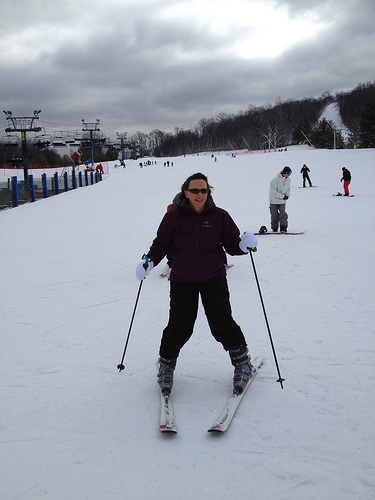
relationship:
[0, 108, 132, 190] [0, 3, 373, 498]
chair lift at ski resort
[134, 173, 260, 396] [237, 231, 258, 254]
skier wearing glove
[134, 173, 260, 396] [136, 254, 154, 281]
skier wearing glove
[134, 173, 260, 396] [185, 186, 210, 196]
skier wearing sunglasses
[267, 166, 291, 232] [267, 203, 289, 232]
skier wearing pants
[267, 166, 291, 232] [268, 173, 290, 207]
skier wearing jacket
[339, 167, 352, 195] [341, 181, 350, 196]
skier wearing pants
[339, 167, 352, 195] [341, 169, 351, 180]
skier wearing jacket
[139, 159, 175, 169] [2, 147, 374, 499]
skiers up on slope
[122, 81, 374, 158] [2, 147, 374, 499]
trees to right of slope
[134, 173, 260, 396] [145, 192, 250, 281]
skier wearing jacket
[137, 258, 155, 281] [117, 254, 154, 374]
hand holding ski pole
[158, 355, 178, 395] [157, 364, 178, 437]
ski boot on top of ski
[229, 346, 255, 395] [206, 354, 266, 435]
ski boot on top of ski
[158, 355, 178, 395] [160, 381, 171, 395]
ski boot placed in binder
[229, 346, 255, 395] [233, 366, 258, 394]
ski boot placed in binder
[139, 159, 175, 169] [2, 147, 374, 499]
skiers located on slope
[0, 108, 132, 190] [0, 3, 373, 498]
chair lift located in ski resort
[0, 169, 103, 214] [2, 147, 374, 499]
fence to left of slope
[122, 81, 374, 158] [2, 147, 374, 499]
trees next to slope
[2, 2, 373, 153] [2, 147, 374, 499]
sky above slope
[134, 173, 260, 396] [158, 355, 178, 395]
skier wearing ski boot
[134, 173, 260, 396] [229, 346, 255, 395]
skier wearing ski boot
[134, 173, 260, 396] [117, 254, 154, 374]
skier holding ski pole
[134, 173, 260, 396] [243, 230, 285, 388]
skier holding ski pole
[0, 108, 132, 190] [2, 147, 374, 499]
chair lift above slope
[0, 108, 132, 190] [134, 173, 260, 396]
chair lift to left of skier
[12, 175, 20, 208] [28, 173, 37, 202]
post next to post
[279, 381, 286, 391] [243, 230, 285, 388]
point on end of ski pole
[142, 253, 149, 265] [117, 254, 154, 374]
strap attached to ski pole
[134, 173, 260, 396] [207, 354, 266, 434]
skier on top of ski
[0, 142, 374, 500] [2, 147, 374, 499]
snow on top of slope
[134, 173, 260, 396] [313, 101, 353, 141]
skier standing on snow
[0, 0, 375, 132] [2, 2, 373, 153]
clouds floating in sky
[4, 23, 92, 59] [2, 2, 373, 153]
clouds floating in sky